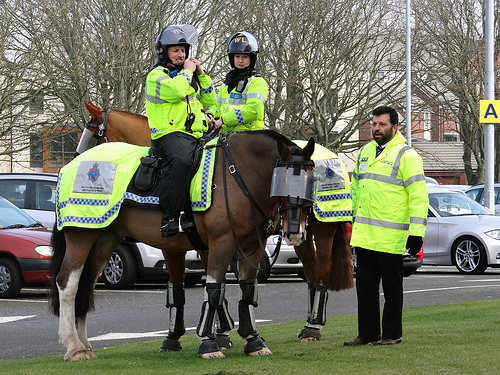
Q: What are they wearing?
A: Fluorescent coats.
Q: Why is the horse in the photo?
A: One of the men are riding it.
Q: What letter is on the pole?
A: A.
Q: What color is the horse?
A: Brown.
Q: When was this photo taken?
A: Daylight.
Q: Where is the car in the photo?
A: Behind the horse.